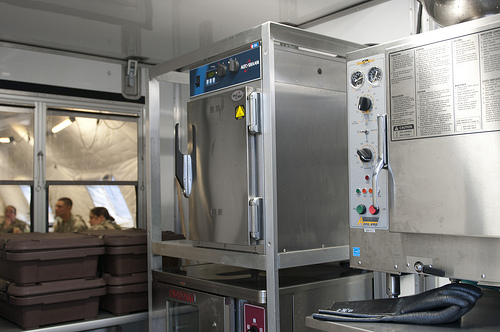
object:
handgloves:
[315, 281, 484, 320]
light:
[47, 115, 77, 135]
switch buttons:
[344, 54, 393, 234]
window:
[41, 106, 142, 185]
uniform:
[50, 213, 88, 235]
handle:
[172, 123, 195, 199]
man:
[49, 197, 87, 233]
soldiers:
[0, 204, 37, 234]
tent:
[2, 105, 140, 232]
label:
[186, 48, 263, 100]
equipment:
[343, 14, 500, 287]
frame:
[142, 20, 376, 331]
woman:
[86, 207, 124, 232]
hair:
[90, 205, 116, 223]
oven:
[170, 45, 349, 253]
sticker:
[233, 103, 246, 120]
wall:
[0, 39, 140, 97]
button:
[367, 204, 381, 217]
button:
[223, 58, 241, 75]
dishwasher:
[143, 20, 368, 330]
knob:
[212, 60, 229, 78]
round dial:
[366, 66, 384, 87]